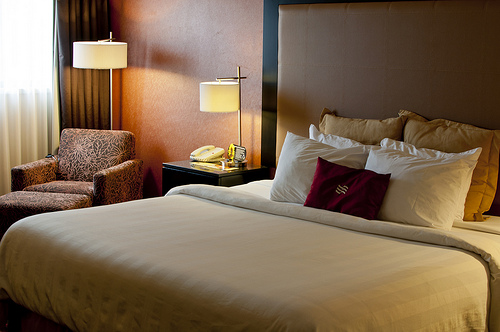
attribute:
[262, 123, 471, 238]
pillow — hotel bed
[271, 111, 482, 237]
pillow — hotel bed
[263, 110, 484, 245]
pillow — hotel bed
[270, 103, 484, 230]
pillow — hotel bed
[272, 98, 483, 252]
pillow — hotel bed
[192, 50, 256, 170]
lamp — small white bedside 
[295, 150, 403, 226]
pillow — small burgundy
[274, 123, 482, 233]
pillow — white 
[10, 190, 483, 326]
blanket — white 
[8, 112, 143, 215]
chair —  brown arm, black 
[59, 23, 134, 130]
lamp — big white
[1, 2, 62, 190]
curtains — white, black , hanging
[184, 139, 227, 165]
telephone — white 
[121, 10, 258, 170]
wall — pink , black line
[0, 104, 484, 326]
bed — red pillow 